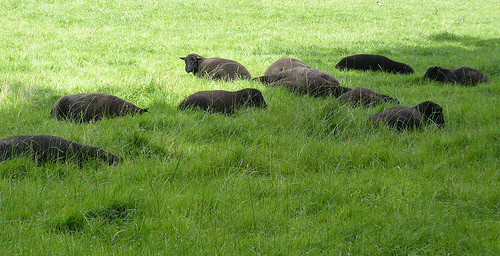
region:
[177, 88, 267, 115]
cow is laying in the grass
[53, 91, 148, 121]
cow is laying in the grass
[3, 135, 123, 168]
cow is laying in the grass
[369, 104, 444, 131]
cow is laying in the grass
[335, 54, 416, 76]
cow is laying in the grass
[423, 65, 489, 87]
cow is laying in the grass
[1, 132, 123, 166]
black animal laying in grass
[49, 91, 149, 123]
black animal laying in grass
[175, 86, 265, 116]
black animal laying in grass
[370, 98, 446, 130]
black animal laying in grass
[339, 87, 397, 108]
black animal laying in grass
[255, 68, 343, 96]
black animal laying in grass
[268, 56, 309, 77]
black animal laying in grass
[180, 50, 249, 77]
black animal laying in grass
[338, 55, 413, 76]
black animal laying in grass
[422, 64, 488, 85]
black animal laying in grass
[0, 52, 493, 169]
Group of animals laying in the grass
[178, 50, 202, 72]
Black face on front of animal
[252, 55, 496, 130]
Animals laying in the shade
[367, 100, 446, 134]
Animal hiding in the grass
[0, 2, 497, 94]
Sun shining on grass in background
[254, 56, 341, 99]
Animal lying on side in grass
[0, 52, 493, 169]
Large group of dark gray animals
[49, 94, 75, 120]
Back of animal laying in glass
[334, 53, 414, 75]
Animal lying near sunny grass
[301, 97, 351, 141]
Clump of tall grass near animals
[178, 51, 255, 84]
An animal looking around.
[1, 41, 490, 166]
A group of animals laying in a field.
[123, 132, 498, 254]
Green grass.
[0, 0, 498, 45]
Sun shining down on the field.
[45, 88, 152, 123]
An animal laying with it's head on the ground.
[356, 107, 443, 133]
Long grass obstructing the view of the animal.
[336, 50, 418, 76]
An all black animal laying down.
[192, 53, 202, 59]
A tag in the animals ear.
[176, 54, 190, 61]
The sheep's ear.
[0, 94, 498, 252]
A shadow being casted over the animals.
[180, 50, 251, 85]
Black animal laying on grass.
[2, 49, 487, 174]
Group of sheep laying in grass.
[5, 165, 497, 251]
Green grass is tall.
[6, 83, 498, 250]
Black sheep resting in shaded are of field.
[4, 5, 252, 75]
One sheep resting in grass with sun shining down.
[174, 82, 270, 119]
Black animal facing right side.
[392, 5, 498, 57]
Shadows are on the ground.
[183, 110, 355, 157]
Grassy area is tall.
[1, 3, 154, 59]
Area of grass that is short.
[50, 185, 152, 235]
Dark area in the grassy field.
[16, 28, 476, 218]
animals on the ground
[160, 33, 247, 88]
dark animal on grass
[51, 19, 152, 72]
light hitting the grass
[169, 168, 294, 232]
shaded area of grass